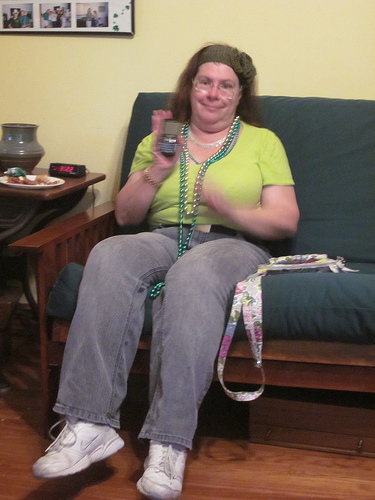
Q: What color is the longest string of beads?
A: Green.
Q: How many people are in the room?
A: 1.